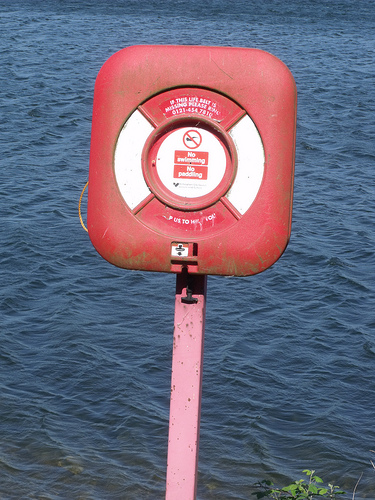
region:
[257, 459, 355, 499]
a part of a bush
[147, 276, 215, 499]
a weathered pink pole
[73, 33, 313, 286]
a red and white sign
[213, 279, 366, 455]
ripples in blue water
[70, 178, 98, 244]
a stray piece of wire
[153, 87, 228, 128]
the message for a missing life boat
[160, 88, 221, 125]
the phone number for reporting a missing life boat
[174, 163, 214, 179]
a prohibition against paddling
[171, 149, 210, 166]
a prohibition against swimming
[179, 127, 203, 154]
a symbol with a message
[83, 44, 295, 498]
empty life belt stand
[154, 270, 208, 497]
faded red paint on a post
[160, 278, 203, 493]
rusty metal post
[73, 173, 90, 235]
yellow rope attached to life belt stand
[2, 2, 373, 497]
calm rippled water behind a post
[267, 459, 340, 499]
a green plant growing next to a rusty old post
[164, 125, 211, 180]
signs warning against swimming and paddling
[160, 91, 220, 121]
telephone number is displayed for reporting a missing life belt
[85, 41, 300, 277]
red and white stand for a life belt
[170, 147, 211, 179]
warning signs are red and white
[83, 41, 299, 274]
a square red and white sign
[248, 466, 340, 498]
the top of a green plant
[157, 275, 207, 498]
a pink pole with chipped paint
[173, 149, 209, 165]
the words "no swimming"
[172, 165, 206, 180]
the words "no paddling"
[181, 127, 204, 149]
a diagram representing "no swimming"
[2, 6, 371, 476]
a large blue lake with little waves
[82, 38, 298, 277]
a red and white life preserver in a red case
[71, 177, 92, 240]
part of a yellow string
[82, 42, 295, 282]
a red and white piece of safety equipment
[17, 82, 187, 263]
Water behind floating device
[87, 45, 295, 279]
Floating device is red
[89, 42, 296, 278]
red device has life raft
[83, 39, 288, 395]
red device is on pink pole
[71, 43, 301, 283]
red device is near water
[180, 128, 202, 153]
device has a warning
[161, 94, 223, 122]
white lettering on device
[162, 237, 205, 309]
latch to open is on bottom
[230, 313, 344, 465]
water is very choppy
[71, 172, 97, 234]
string on side of device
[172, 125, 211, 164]
A sign says no swimming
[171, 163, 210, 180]
A no paddling sign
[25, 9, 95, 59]
The water is blue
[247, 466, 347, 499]
green plant growing in water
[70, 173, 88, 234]
A thin yellow cord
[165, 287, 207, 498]
Arm for signs is pink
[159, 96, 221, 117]
Number to call if life eject is missing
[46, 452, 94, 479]
A rock can be seen under water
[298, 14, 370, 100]
Water is a bit choppy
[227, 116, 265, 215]
White portion from a red and white circle